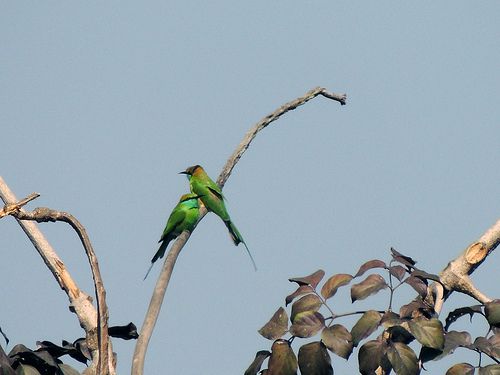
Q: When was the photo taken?
A: Daytime.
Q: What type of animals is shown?
A: Birds.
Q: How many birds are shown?
A: Two.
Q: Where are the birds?
A: Tree branches.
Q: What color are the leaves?
A: Purple.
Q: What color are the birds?
A: Green.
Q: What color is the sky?
A: Blue.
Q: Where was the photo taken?
A: In a tree.